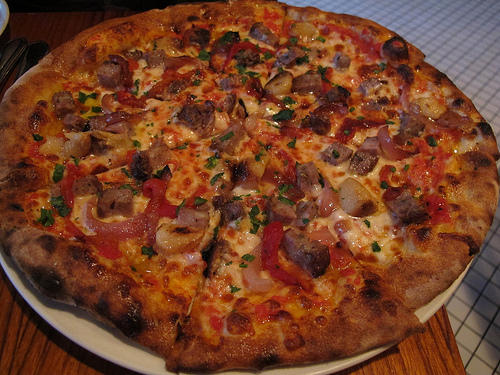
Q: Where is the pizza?
A: On a white plate.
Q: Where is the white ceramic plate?
A: On a wooden table.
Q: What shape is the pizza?
A: Round.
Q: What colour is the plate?
A: Beige.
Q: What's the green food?
A: Peppers.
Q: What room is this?
A: Kitchen.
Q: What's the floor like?
A: Tiles.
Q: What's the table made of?
A: Wood.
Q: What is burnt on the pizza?
A: Crust.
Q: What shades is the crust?
A: Brown and black.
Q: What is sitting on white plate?
A: Pizza.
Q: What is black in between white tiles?
A: Grout.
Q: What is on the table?
A: One round multi-topping pizza.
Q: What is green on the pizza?
A: Sprinkled oregano.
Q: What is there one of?
A: Large round pizza.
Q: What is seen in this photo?
A: A pizza on a plate.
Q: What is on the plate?
A: Pizza.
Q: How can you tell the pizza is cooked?
A: Crust is brown.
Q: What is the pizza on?
A: A plate.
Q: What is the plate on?
A: A table.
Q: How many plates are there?
A: One.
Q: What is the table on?
A: The floor.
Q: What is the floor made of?
A: Tile.